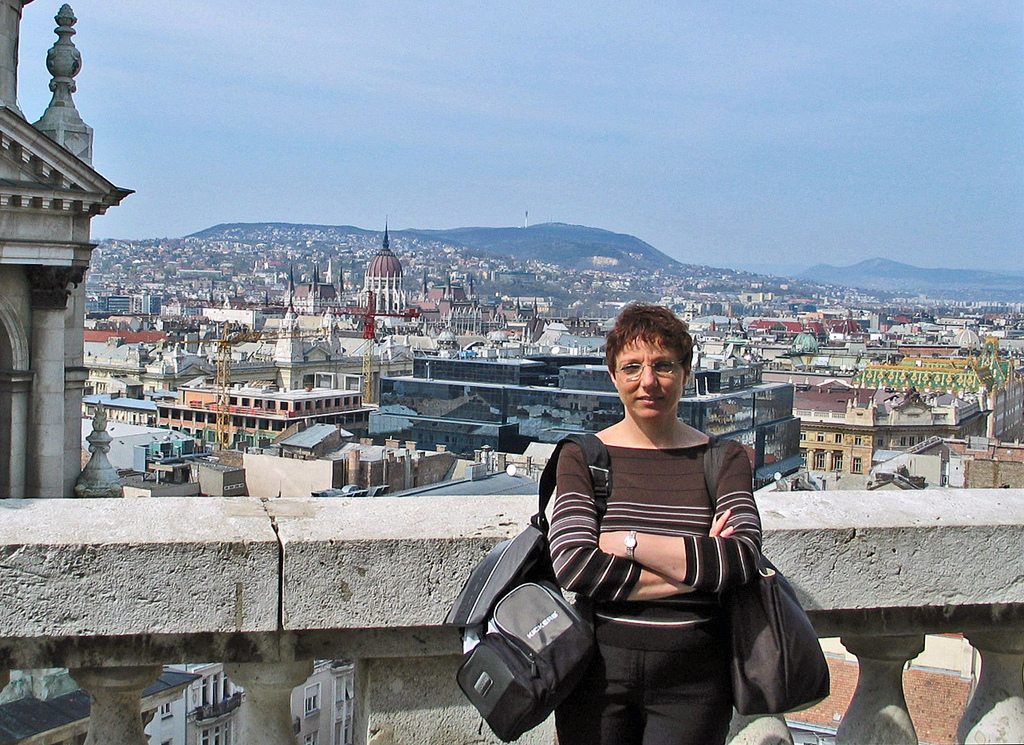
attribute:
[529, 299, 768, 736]
woman — standing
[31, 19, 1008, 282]
sky — blue, hazy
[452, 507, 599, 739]
black bag — gray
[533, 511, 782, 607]
arms — crossed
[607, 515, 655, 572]
wrist — woman's